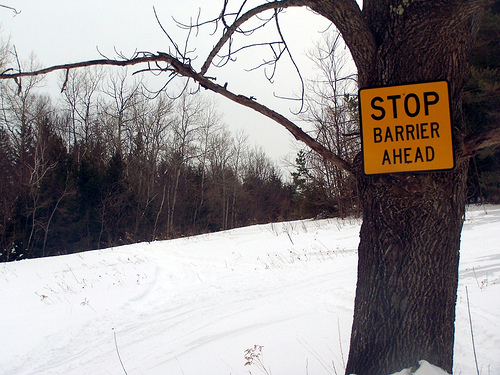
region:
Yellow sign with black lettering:
[356, 78, 456, 176]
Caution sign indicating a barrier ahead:
[356, 86, 456, 176]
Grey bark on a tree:
[368, 211, 443, 356]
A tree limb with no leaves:
[8, 52, 362, 179]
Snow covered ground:
[1, 253, 179, 371]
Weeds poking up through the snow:
[253, 243, 348, 265]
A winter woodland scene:
[18, 15, 489, 361]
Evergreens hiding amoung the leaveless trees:
[72, 150, 134, 245]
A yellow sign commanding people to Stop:
[356, 79, 458, 173]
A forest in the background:
[13, 115, 338, 233]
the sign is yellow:
[340, 71, 491, 219]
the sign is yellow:
[379, 78, 436, 200]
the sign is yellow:
[329, 58, 434, 266]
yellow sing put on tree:
[341, 85, 459, 227]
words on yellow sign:
[330, 87, 445, 191]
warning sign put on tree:
[312, 10, 466, 235]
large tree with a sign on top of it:
[5, 17, 489, 352]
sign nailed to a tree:
[240, 54, 472, 308]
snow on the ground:
[64, 238, 284, 373]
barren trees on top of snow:
[0, 12, 215, 247]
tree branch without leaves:
[5, 47, 283, 152]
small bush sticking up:
[232, 327, 266, 374]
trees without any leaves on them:
[145, 131, 329, 232]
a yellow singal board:
[336, 68, 466, 178]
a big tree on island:
[336, 19, 455, 371]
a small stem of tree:
[127, 48, 365, 183]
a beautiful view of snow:
[13, 218, 475, 373]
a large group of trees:
[8, 57, 353, 224]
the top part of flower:
[236, 336, 278, 370]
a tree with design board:
[333, 5, 456, 372]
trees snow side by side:
[93, 148, 283, 350]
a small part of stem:
[466, 125, 498, 156]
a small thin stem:
[456, 281, 496, 373]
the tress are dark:
[87, 142, 285, 279]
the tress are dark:
[79, 147, 167, 227]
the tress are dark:
[106, 147, 257, 225]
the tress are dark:
[116, 174, 226, 244]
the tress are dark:
[85, 125, 145, 180]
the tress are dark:
[100, 121, 128, 142]